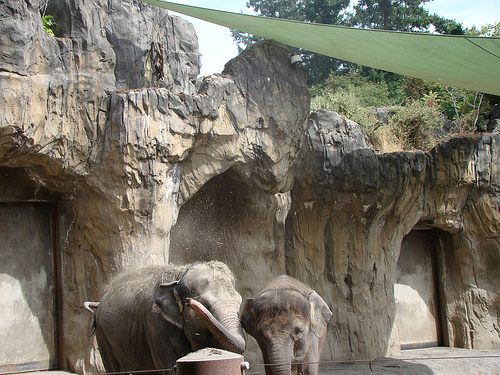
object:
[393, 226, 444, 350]
door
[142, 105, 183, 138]
rocks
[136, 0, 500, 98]
canopy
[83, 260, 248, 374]
elephant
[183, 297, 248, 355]
trunk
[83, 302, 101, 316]
tail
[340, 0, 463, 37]
trees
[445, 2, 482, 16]
sky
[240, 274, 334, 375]
elephant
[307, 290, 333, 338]
ears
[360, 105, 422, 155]
plants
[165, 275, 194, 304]
dust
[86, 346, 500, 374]
fence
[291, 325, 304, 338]
eye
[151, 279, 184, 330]
ear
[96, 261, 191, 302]
back